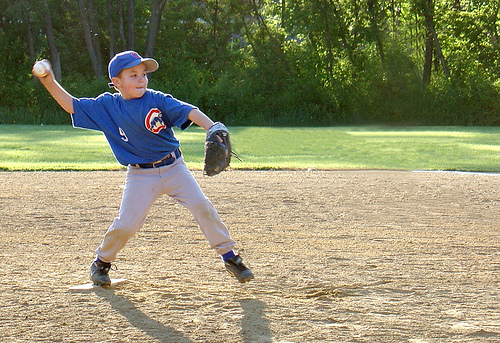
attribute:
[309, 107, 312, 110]
leaf — green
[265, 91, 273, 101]
leaf — green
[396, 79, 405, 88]
leaf — green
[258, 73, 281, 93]
leaf — green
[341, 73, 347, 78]
leaf — green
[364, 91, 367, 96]
leaf — green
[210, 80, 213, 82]
leaf — green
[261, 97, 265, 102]
leaf — green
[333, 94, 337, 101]
leaf — green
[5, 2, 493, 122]
foliage — dense